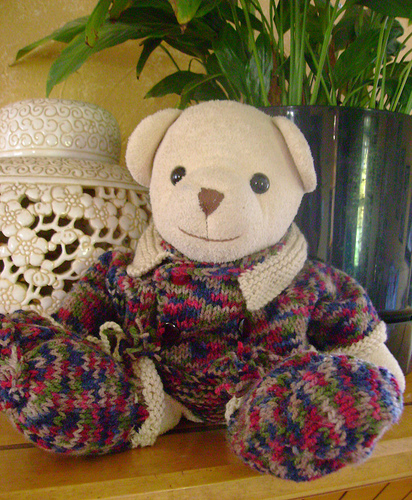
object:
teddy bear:
[0, 98, 404, 482]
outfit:
[0, 223, 406, 484]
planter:
[243, 104, 412, 376]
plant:
[8, 1, 412, 116]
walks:
[0, 0, 411, 167]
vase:
[0, 99, 153, 318]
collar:
[124, 217, 307, 311]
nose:
[197, 187, 224, 217]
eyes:
[170, 165, 271, 196]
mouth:
[174, 225, 241, 244]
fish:
[132, 456, 216, 497]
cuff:
[325, 316, 385, 361]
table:
[0, 373, 411, 499]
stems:
[234, 0, 395, 112]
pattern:
[0, 97, 124, 169]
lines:
[0, 449, 310, 499]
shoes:
[0, 306, 402, 484]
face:
[149, 100, 304, 264]